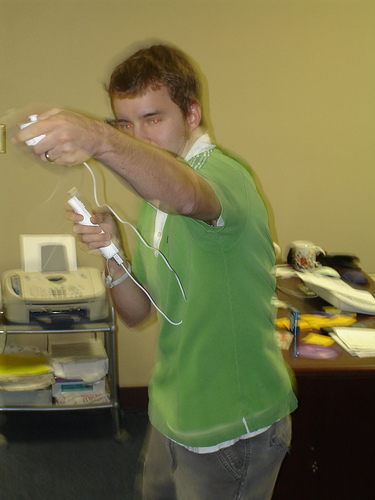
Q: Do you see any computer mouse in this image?
A: No, there are no computer mice.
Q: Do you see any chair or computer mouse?
A: No, there are no computer mice or chairs.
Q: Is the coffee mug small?
A: Yes, the coffee mug is small.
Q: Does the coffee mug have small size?
A: Yes, the coffee mug is small.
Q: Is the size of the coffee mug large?
A: No, the coffee mug is small.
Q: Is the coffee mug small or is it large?
A: The coffee mug is small.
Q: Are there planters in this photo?
A: No, there are no planters.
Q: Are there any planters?
A: No, there are no planters.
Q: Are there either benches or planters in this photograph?
A: No, there are no planters or benches.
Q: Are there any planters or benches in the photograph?
A: No, there are no planters or benches.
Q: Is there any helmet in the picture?
A: No, there are no helmets.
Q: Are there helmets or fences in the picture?
A: No, there are no helmets or fences.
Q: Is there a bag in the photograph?
A: No, there are no bags.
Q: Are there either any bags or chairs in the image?
A: No, there are no bags or chairs.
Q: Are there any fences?
A: No, there are no fences.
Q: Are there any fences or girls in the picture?
A: No, there are no fences or girls.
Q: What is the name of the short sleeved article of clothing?
A: The clothing item is a shirt.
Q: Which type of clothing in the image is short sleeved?
A: The clothing is a shirt.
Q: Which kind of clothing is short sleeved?
A: The clothing is a shirt.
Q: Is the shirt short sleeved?
A: Yes, the shirt is short sleeved.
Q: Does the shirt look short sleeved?
A: Yes, the shirt is short sleeved.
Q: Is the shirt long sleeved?
A: No, the shirt is short sleeved.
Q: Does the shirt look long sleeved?
A: No, the shirt is short sleeved.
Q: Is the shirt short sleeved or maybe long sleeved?
A: The shirt is short sleeved.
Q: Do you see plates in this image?
A: No, there are no plates.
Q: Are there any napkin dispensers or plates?
A: No, there are no plates or napkin dispensers.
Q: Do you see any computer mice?
A: No, there are no computer mice.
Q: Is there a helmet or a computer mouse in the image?
A: No, there are no computer mice or helmets.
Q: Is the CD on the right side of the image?
A: Yes, the CD is on the right of the image.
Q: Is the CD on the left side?
A: No, the CD is on the right of the image.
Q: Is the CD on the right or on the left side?
A: The CD is on the right of the image.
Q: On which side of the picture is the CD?
A: The CD is on the right of the image.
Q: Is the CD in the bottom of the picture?
A: Yes, the CD is in the bottom of the image.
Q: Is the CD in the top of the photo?
A: No, the CD is in the bottom of the image.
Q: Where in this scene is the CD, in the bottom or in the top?
A: The CD is in the bottom of the image.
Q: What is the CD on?
A: The CD is on the desk.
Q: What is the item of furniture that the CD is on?
A: The piece of furniture is a desk.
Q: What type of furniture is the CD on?
A: The CD is on the desk.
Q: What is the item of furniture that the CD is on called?
A: The piece of furniture is a desk.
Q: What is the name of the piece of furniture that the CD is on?
A: The piece of furniture is a desk.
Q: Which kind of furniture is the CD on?
A: The CD is on the desk.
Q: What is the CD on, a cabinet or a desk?
A: The CD is on a desk.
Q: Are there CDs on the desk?
A: Yes, there is a CD on the desk.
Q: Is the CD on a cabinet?
A: No, the CD is on the desk.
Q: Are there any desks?
A: Yes, there is a desk.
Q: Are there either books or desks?
A: Yes, there is a desk.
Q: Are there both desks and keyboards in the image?
A: No, there is a desk but no keyboards.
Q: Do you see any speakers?
A: No, there are no speakers.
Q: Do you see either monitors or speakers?
A: No, there are no speakers or monitors.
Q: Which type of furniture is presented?
A: The furniture is a desk.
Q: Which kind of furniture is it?
A: The piece of furniture is a desk.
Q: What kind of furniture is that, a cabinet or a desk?
A: This is a desk.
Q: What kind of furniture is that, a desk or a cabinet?
A: This is a desk.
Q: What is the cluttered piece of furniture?
A: The piece of furniture is a desk.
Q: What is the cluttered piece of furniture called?
A: The piece of furniture is a desk.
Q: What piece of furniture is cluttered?
A: The piece of furniture is a desk.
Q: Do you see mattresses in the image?
A: No, there are no mattresses.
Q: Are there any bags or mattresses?
A: No, there are no mattresses or bags.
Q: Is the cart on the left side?
A: Yes, the cart is on the left of the image.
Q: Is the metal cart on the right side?
A: No, the cart is on the left of the image.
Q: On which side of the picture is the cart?
A: The cart is on the left of the image.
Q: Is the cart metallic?
A: Yes, the cart is metallic.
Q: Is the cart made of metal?
A: Yes, the cart is made of metal.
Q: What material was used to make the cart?
A: The cart is made of metal.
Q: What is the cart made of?
A: The cart is made of metal.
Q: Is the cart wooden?
A: No, the cart is metallic.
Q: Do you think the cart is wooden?
A: No, the cart is metallic.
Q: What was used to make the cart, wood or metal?
A: The cart is made of metal.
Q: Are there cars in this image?
A: No, there are no cars.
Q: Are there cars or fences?
A: No, there are no cars or fences.